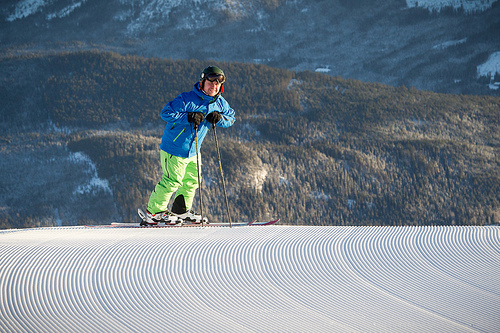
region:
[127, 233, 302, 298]
curved lines on snow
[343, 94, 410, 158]
tree tops on hill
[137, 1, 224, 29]
patches of snow on mountain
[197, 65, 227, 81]
blacke helmet on head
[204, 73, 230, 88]
goggles on forehead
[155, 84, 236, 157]
blue jacket on skier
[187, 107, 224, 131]
black gloves on hand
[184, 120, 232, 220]
poles in front of skier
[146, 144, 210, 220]
green pants on skier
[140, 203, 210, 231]
boots on top of skis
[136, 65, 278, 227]
man on skis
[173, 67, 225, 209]
man wearing a black helmet and a blue coat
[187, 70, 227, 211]
man wearing black gloves and green ski pants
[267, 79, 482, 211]
tree covered mountains in the background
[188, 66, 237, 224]
man holding two ski poles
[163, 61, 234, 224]
man outside on a mountain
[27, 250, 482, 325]
lined marks on the ground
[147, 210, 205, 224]
man's black and white ski boots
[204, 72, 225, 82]
ski goggles on the man's head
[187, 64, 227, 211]
man wearing a blue coat holding ski poles in his hands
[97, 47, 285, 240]
man smiling on skiis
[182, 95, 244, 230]
hands holding ski poles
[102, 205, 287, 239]
skii's on the smooth snow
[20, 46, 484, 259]
trees standing in the background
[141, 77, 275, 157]
man wearing a blue ski jacket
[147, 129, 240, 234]
man wearing a neon green pants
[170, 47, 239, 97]
man wearing a helmet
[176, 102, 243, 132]
man wearing black gloves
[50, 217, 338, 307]
ski marks on the ground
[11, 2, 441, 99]
mountainous terrain in the background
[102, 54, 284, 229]
man skiing on slope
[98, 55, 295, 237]
man skiing on skiis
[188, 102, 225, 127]
warm black sport gloves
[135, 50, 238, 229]
man holding ski poles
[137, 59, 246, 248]
man wearing blue ski jacket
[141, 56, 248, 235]
man wearing dark green ski helmet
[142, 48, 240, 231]
man wearing protective safety goggles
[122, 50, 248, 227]
man wearing lime green ski pants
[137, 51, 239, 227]
man wearing black gloves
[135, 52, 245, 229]
man wearing skis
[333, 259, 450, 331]
snow on the ground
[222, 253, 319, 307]
ruts in the snow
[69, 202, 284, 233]
skis on the skier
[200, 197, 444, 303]
slope top for skiing down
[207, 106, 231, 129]
glove on skier's hand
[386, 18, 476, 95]
mountains behind the skier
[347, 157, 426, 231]
trees behind the skier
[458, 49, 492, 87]
snow on the mountain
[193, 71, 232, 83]
goggles on the skier's head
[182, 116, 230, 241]
skier's metal ski pole's